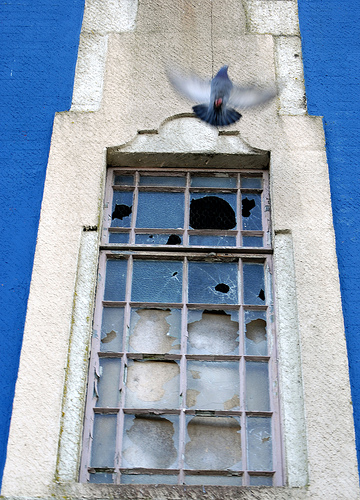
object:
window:
[90, 174, 260, 315]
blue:
[0, 168, 34, 236]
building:
[1, 0, 359, 498]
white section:
[78, 31, 102, 106]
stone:
[133, 312, 167, 345]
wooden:
[103, 172, 114, 230]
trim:
[222, 189, 258, 206]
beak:
[223, 61, 232, 71]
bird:
[160, 61, 289, 128]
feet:
[214, 97, 224, 107]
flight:
[164, 68, 285, 113]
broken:
[181, 185, 236, 233]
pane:
[181, 185, 248, 243]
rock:
[209, 276, 236, 295]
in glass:
[171, 257, 264, 317]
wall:
[234, 9, 290, 65]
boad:
[104, 320, 259, 418]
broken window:
[95, 251, 262, 413]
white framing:
[73, 248, 94, 330]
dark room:
[196, 203, 221, 222]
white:
[186, 86, 205, 97]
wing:
[160, 62, 213, 107]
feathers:
[218, 105, 237, 129]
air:
[309, 3, 358, 93]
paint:
[261, 172, 271, 245]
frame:
[174, 167, 246, 202]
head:
[220, 62, 232, 77]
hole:
[200, 200, 227, 224]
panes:
[124, 170, 240, 246]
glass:
[139, 170, 184, 192]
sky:
[316, 34, 329, 56]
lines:
[128, 168, 138, 250]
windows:
[69, 150, 273, 437]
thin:
[145, 275, 170, 299]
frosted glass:
[130, 192, 184, 235]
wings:
[228, 81, 286, 111]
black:
[221, 115, 229, 127]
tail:
[191, 109, 238, 130]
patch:
[159, 198, 188, 222]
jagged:
[187, 309, 210, 335]